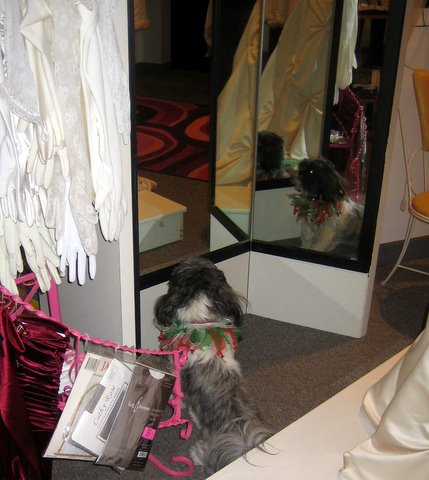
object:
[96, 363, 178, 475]
magazine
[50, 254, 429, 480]
floor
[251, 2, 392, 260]
mirror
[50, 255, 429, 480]
carpet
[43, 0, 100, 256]
clothes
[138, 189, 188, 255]
box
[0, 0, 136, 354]
wardrobe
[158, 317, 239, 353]
collar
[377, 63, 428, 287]
chair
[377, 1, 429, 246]
wall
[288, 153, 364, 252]
reflection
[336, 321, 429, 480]
sheet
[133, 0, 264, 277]
mirrors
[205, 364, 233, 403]
fur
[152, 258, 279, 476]
dog